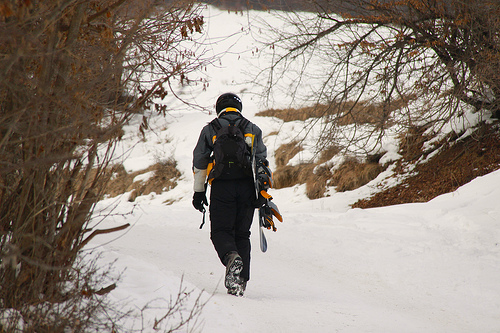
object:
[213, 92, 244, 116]
helmet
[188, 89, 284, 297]
man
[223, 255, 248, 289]
boots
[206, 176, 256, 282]
pants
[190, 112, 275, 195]
jacket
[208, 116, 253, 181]
backpack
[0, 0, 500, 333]
snow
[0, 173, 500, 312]
ground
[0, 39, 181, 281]
bush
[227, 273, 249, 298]
shoes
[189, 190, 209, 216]
gloves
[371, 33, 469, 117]
trees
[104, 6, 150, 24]
branches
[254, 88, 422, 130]
dirt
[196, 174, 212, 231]
skis